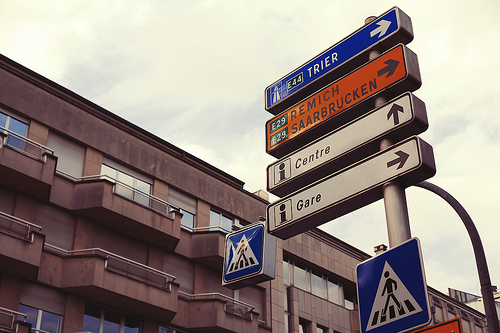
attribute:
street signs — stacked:
[264, 6, 434, 241]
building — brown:
[1, 54, 495, 328]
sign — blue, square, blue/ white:
[218, 226, 276, 286]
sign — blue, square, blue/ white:
[357, 237, 431, 332]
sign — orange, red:
[267, 44, 408, 149]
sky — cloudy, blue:
[1, 1, 498, 193]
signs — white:
[267, 93, 437, 233]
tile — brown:
[292, 287, 350, 332]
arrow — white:
[365, 18, 393, 39]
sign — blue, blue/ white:
[265, 6, 407, 111]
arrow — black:
[384, 102, 406, 127]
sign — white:
[266, 90, 415, 193]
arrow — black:
[386, 151, 408, 169]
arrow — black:
[376, 58, 400, 76]